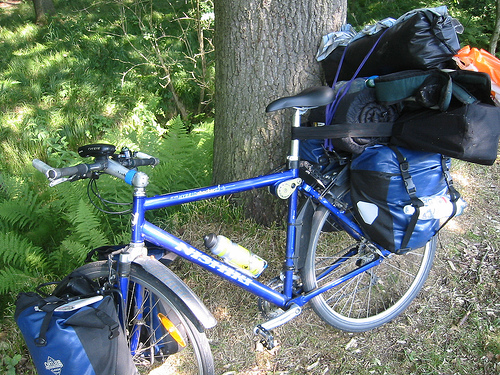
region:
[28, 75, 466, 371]
Blue bike in the forest.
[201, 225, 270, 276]
Water bottle on the bike.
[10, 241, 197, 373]
Bags on front of the bike.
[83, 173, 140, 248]
Wire controlling the breaks.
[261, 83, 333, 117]
Seat of the bike.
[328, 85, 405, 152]
Sleeping bag on the bike.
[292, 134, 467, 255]
Bags on the back of the bike.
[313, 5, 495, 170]
The biker's gear on the back of the bike.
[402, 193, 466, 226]
Water bottle cinched on the bag.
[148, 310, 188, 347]
Reflector on the front wheel.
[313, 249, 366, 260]
metal spoke on tire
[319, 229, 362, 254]
metal spoke on tire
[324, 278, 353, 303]
metal spoke on tire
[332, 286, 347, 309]
metal spoke on tire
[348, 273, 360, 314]
metal spoke on tire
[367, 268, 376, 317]
metal spoke on tire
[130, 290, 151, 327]
metal spoke on tire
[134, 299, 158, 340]
metal spoke on tire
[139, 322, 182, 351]
metal spoke on tire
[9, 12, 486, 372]
a blue bicycle packed for travelling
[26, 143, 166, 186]
the handle bars of a bicycle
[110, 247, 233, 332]
the fender of a bicycle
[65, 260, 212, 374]
the front wheel of a bicycle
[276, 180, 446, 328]
the rear wheel of a bicycle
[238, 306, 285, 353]
the pedal of a bicycle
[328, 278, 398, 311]
the spokes of a bicycle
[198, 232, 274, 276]
the water bottle of a bicycle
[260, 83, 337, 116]
the seat of a bicycle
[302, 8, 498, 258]
bags attached to a bicycle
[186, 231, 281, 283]
plastic water bottle on bike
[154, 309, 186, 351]
orange reflector on bike tire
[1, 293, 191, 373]
blue and black bag on front of tire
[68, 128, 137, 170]
black colored light on handle bar of bicycle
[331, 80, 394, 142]
black rolled up sleeping bag on bike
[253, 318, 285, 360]
black pedal on bicycle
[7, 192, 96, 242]
green ferns on ground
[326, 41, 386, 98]
blue cord holding items on bicycle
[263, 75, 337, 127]
black padded bicycle seat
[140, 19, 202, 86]
brown bush with no leaves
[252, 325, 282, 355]
A pedal on the bicycle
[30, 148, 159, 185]
The handlebars of the bicycle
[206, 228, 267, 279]
A water bottle connected to the bicycle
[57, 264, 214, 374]
The front tire of the bicycle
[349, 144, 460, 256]
A bag connected to the bicycle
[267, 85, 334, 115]
A seat on the bicycle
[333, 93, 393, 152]
A sleep bag connected to the bicycle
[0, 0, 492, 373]
Grass near the bicycle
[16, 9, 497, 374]
A bicycle parked by a tree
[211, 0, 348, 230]
A tree near the bicycle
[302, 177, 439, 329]
tire is attached to bicycle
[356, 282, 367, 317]
metal spoke on tire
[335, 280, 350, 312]
metal spoke on tire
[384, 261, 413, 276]
metal spoke on tire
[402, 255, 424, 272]
metal spoke on tire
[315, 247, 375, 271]
metal spoke on tire